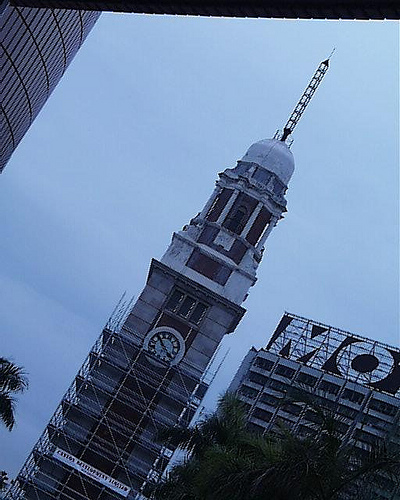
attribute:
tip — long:
[283, 44, 336, 139]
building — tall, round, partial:
[1, 139, 295, 499]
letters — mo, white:
[271, 313, 395, 386]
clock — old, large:
[143, 326, 186, 368]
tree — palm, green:
[147, 381, 399, 500]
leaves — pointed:
[157, 395, 398, 500]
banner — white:
[53, 446, 131, 498]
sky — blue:
[2, 6, 398, 479]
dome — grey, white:
[241, 139, 295, 185]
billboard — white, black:
[266, 311, 400, 398]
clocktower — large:
[1, 256, 247, 499]